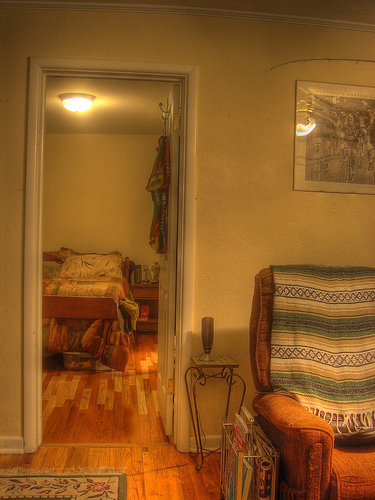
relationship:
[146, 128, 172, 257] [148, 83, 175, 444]
clothes hanging on door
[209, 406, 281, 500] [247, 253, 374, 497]
magazine rack next to chair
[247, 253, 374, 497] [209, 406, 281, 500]
chair next to magazine rack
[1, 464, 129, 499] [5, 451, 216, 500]
area rug on ground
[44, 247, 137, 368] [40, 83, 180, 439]
bed in room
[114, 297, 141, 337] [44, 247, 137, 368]
hats hanging off bed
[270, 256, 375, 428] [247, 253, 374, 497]
blanket draped on chair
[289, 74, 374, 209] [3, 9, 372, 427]
picture hanging on wall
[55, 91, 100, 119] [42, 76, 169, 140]
light on ceiling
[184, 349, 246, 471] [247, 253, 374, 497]
table behind chair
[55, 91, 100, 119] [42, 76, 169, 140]
light attached to ceiling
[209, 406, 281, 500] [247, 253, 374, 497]
book rack on side of chair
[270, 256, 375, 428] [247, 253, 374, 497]
blanket over armchair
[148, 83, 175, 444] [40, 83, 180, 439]
door to bedroom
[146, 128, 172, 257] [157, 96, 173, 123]
clothing hanging on hooks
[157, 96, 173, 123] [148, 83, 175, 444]
hooks on door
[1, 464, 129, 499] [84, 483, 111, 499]
area rug with pattern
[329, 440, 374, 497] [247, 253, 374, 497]
cushion on armchair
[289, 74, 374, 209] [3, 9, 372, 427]
art on wall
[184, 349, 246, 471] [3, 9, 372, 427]
table against wall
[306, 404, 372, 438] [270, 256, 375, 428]
fringe on blanket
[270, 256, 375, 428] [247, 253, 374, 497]
blanket hanging over chair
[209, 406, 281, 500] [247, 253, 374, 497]
magazine rack by chair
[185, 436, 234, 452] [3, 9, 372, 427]
trim on wall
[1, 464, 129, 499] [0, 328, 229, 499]
rug on floor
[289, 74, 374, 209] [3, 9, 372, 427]
artwork hanging on wall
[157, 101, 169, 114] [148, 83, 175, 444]
hooks on back of door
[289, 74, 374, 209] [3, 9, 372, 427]
picture on wall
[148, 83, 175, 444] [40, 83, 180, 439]
door of bedroom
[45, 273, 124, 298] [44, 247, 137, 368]
comforter on top of bed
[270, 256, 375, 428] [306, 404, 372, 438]
blanket with fringe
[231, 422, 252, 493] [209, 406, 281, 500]
magazines inside rack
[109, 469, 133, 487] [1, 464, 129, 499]
corner of rug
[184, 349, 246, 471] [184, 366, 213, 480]
table with legs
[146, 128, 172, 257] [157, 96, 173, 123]
clothes hanging on hooks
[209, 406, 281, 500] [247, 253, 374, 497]
magazine rack by sofa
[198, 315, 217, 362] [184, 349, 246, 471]
vase on table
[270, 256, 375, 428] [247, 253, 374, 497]
blanket on chair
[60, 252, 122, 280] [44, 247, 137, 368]
pillow laying on bed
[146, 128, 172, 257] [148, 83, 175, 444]
shirts hanging on door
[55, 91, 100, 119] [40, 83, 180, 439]
light in room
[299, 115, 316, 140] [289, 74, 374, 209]
reflection in picture